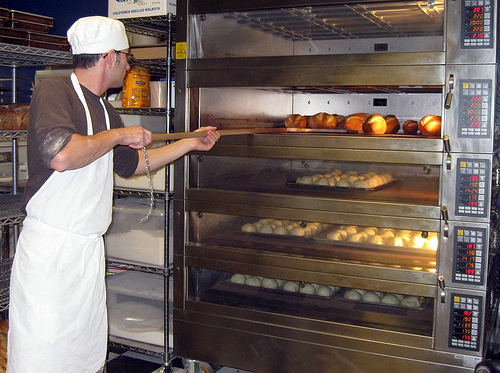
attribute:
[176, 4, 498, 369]
ovens — stacked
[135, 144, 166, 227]
metal chain — small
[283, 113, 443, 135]
bread — cooked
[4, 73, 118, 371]
apron — man's, white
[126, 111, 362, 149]
paddle — large, wooden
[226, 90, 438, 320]
bread — baking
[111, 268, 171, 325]
plastic container — large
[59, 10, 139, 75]
hat — white, man's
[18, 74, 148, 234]
shirt — brown, man's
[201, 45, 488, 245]
shelves — metal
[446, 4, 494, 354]
numbers — red, orange